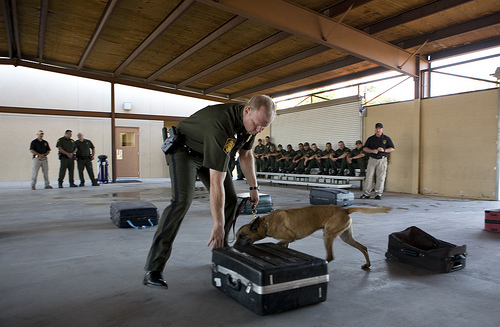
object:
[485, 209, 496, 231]
suitcase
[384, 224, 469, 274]
suitcase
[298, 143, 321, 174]
person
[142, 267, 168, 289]
shoe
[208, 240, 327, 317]
case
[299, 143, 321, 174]
sitting down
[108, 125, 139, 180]
door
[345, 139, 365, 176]
person sitting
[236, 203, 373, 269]
brown dog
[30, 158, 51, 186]
pants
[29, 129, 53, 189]
man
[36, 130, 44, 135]
hat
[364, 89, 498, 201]
wall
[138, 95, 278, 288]
officer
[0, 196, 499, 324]
floor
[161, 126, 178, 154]
gun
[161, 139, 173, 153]
holster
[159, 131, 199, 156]
hip